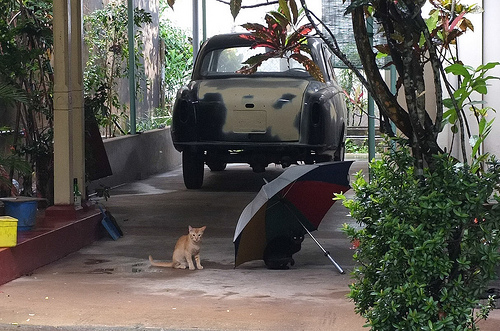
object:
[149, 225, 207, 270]
cat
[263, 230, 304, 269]
cat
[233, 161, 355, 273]
umbrella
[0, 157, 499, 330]
ground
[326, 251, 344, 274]
handle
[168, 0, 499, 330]
plant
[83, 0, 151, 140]
plant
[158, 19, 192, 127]
plant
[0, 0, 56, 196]
plant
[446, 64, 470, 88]
leaf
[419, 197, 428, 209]
leaf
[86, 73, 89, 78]
leaf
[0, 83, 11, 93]
leaf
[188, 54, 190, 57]
leaf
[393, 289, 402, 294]
leaf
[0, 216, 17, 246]
container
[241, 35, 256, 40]
spot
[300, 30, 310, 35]
spot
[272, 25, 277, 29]
spot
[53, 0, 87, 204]
post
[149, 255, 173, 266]
tail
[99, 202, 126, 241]
shovel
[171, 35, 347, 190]
car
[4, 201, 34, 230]
bucket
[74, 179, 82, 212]
fluid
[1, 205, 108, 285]
ledge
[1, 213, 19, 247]
buckets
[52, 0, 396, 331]
carport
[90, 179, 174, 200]
moisture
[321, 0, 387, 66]
building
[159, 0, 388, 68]
distance